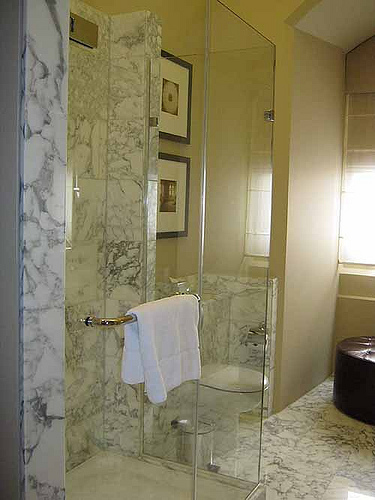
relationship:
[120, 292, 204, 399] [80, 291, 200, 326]
bath towel hanging on bar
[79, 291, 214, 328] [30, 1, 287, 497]
bar in shower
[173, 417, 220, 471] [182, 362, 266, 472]
trash can by toilet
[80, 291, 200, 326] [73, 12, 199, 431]
bar on shower door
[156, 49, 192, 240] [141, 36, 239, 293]
art hanging on wall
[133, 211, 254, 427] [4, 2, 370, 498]
window in bathroom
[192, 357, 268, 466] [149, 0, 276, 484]
toilet behind door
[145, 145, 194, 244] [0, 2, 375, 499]
picture on bathroom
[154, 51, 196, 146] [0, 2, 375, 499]
picture on bathroom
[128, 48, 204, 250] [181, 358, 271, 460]
art above toilet